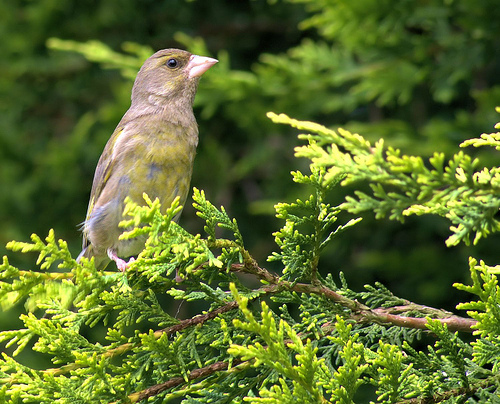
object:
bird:
[72, 46, 222, 273]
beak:
[188, 54, 220, 77]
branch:
[312, 263, 500, 341]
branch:
[170, 258, 277, 284]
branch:
[159, 286, 275, 337]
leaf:
[226, 281, 331, 403]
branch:
[122, 316, 359, 404]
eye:
[167, 59, 177, 68]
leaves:
[314, 1, 499, 87]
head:
[130, 48, 219, 107]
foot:
[106, 247, 134, 271]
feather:
[76, 203, 116, 233]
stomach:
[134, 126, 192, 212]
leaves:
[2, 110, 499, 403]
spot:
[146, 161, 159, 180]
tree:
[1, 1, 88, 217]